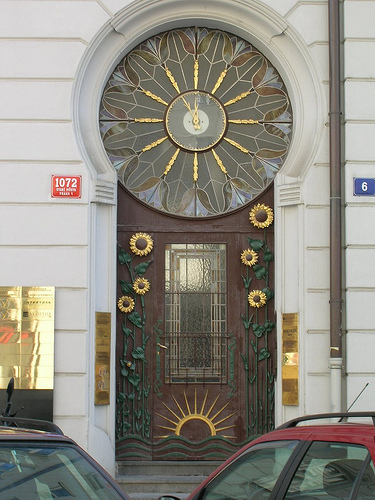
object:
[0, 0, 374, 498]
building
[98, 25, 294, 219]
clock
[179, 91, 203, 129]
hands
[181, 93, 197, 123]
clock hand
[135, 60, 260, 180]
sun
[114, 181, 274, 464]
door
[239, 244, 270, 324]
flowers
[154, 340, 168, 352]
handle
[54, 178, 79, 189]
numbers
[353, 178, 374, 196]
sign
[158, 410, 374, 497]
car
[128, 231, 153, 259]
daisies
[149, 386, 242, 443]
sun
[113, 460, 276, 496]
steps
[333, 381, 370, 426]
antenna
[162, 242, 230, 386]
glass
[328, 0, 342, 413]
pipe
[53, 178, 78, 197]
print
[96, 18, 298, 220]
window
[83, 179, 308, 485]
frame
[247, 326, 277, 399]
green leaf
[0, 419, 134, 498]
car